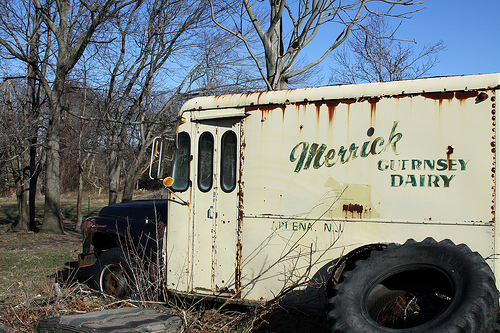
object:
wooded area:
[0, 0, 500, 332]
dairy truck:
[61, 72, 500, 330]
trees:
[0, 0, 445, 232]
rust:
[175, 87, 494, 131]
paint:
[84, 195, 171, 287]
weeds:
[0, 193, 348, 331]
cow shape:
[322, 176, 381, 220]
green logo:
[287, 121, 469, 189]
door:
[192, 117, 242, 299]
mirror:
[150, 135, 168, 180]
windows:
[169, 132, 192, 192]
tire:
[326, 235, 500, 333]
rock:
[34, 305, 185, 333]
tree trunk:
[35, 10, 65, 238]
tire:
[91, 261, 148, 302]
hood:
[99, 199, 168, 222]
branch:
[0, 0, 445, 333]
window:
[220, 130, 238, 192]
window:
[198, 132, 214, 194]